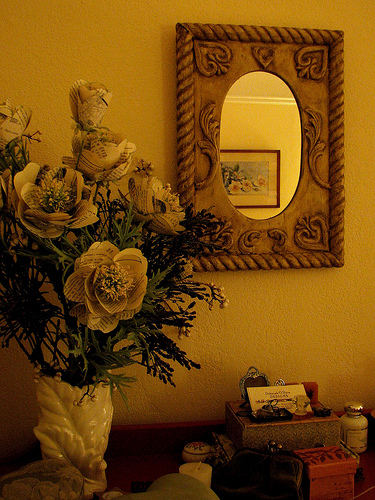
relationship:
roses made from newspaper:
[1, 79, 186, 334] [2, 77, 187, 333]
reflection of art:
[220, 149, 281, 209] [220, 149, 280, 209]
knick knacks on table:
[0, 366, 374, 499] [0, 408, 374, 499]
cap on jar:
[344, 402, 363, 418] [341, 413, 367, 454]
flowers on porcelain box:
[184, 441, 207, 453] [183, 440, 211, 462]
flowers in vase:
[184, 441, 207, 453] [32, 369, 116, 499]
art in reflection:
[220, 149, 280, 209] [220, 149, 281, 209]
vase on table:
[32, 369, 116, 499] [0, 408, 374, 499]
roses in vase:
[1, 79, 186, 334] [32, 369, 116, 499]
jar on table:
[341, 413, 367, 454] [0, 408, 374, 499]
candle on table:
[178, 460, 212, 489] [0, 408, 374, 499]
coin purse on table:
[212, 439, 305, 499] [0, 408, 374, 499]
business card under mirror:
[244, 384, 312, 415] [175, 23, 345, 273]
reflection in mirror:
[220, 149, 281, 209] [175, 23, 345, 273]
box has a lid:
[292, 444, 357, 499] [291, 444, 357, 480]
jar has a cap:
[341, 413, 367, 454] [344, 402, 363, 418]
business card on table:
[244, 384, 312, 415] [0, 408, 374, 499]